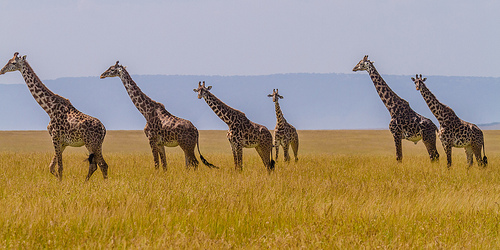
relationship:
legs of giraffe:
[395, 132, 405, 164] [353, 54, 441, 163]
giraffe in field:
[0, 51, 112, 181] [0, 125, 497, 248]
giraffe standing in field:
[192, 81, 276, 175] [0, 125, 497, 248]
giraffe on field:
[98, 58, 218, 171] [1, 115, 496, 244]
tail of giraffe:
[479, 131, 487, 176] [406, 67, 485, 179]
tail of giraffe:
[266, 137, 280, 173] [187, 74, 287, 172]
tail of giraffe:
[191, 130, 220, 172] [94, 52, 219, 183]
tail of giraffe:
[85, 129, 111, 163] [2, 48, 119, 187]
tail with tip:
[479, 131, 487, 176] [480, 155, 487, 165]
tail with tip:
[266, 137, 280, 173] [267, 158, 276, 170]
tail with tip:
[191, 130, 220, 172] [197, 154, 217, 171]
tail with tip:
[85, 129, 111, 163] [82, 153, 102, 169]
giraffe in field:
[0, 51, 112, 181] [0, 163, 497, 248]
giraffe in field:
[98, 58, 218, 171] [0, 163, 497, 248]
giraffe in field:
[192, 77, 274, 177] [0, 163, 497, 248]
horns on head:
[197, 75, 210, 89] [192, 80, 212, 100]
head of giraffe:
[185, 57, 257, 147] [195, 70, 287, 186]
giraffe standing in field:
[410, 73, 490, 171] [2, 152, 498, 247]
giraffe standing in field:
[353, 54, 441, 163] [2, 152, 498, 247]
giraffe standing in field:
[269, 87, 301, 165] [2, 152, 498, 247]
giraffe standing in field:
[0, 51, 112, 181] [2, 152, 498, 247]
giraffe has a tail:
[2, 54, 111, 179] [86, 129, 104, 165]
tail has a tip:
[86, 129, 104, 165] [84, 151, 95, 163]